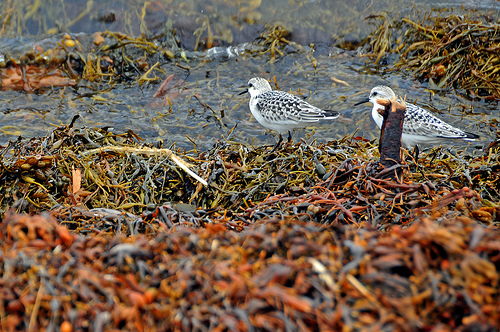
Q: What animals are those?
A: Birds.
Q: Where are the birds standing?
A: In the water.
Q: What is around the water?
A: Grass.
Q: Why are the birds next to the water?
A: Food.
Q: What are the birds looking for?
A: Worms.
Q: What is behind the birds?
A: Water.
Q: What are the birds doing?
A: Standing.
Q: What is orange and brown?
A: The seaweed.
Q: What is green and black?
A: The seaweed.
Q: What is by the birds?
A: The water.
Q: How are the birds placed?
A: One behind the other.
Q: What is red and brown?
A: The leaves.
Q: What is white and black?
A: The birds.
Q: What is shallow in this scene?
A: The water.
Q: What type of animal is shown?
A: Birds.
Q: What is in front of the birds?
A: Water.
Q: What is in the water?
A: Grass.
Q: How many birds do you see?
A: Two.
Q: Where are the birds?
A: On the ground.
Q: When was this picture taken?
A: During the day.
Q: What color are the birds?
A: White and black.